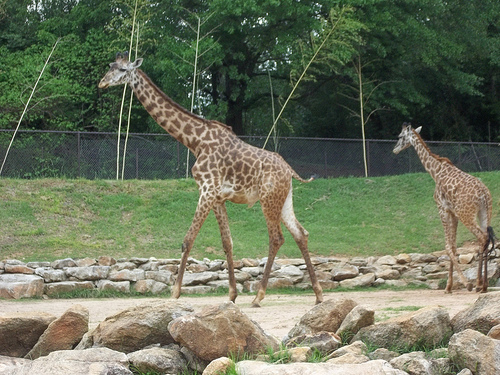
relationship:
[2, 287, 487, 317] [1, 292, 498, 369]
path between rocks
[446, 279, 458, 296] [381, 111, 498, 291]
hoof of giraffe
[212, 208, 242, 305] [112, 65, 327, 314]
leg of giraffe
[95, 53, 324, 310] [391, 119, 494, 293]
giraffe with its baby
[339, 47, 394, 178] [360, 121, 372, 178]
tree with thin trunk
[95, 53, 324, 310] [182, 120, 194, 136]
giraffe has spot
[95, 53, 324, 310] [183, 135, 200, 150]
giraffe has spot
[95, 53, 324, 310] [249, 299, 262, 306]
giraffe has hoof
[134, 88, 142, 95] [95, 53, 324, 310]
spot on giraffe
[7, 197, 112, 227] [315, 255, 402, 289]
grass growing stone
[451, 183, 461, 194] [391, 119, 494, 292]
spots on baby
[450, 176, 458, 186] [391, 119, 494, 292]
spots on baby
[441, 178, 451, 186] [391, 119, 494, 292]
spots on baby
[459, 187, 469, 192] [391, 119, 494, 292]
spots on baby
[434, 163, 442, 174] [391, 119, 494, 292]
spots on baby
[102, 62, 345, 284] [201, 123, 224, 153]
giraffe has spot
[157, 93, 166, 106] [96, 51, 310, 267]
spot on giraffe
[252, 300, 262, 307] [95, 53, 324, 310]
hoof of giraffe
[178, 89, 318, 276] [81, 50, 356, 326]
leg of giraffe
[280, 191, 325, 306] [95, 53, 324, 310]
leg of giraffe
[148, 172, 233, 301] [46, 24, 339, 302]
leg of giraffe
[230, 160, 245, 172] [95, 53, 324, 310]
spot on giraffe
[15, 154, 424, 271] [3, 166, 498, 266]
grass covered slope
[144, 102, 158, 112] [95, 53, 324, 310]
spot on giraffe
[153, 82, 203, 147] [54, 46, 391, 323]
spot on giraffe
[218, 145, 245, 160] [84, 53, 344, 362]
brown spot on giraffe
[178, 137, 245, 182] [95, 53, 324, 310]
spot on giraffe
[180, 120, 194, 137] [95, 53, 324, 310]
spot on giraffe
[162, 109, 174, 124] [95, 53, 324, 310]
spot on giraffe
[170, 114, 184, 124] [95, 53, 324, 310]
spot on giraffe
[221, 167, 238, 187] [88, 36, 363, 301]
brown spot on giraffe